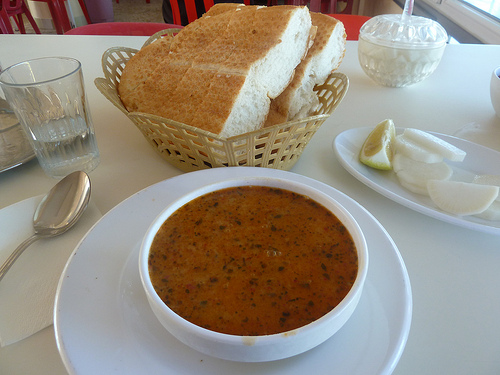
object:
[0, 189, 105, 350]
napkin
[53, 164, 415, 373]
plate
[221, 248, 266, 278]
green seasonings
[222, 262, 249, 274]
seasonings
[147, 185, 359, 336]
orange soup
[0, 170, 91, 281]
silver spoon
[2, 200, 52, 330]
white napkin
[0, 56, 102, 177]
cup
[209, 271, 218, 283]
herb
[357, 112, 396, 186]
lemon wedge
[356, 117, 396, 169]
lemon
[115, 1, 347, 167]
bread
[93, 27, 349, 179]
breadbasket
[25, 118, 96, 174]
water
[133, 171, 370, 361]
white bowl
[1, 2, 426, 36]
red chairs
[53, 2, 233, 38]
chair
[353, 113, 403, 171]
slice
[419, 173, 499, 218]
slice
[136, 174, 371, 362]
bowl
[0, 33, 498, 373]
table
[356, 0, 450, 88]
container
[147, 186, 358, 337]
soup